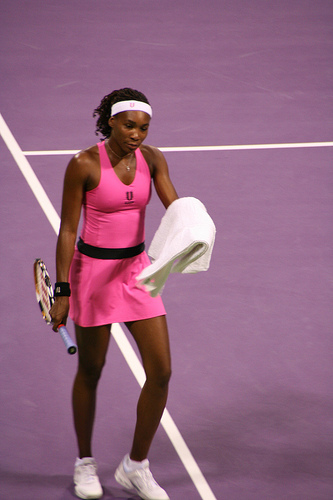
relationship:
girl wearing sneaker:
[48, 87, 180, 499] [73, 455, 104, 499]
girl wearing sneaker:
[48, 87, 180, 499] [114, 452, 171, 499]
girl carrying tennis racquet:
[48, 87, 180, 499] [33, 258, 78, 356]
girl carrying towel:
[48, 87, 180, 499] [136, 196, 218, 298]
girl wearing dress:
[48, 87, 180, 499] [69, 141, 168, 328]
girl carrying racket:
[48, 87, 180, 499] [33, 258, 78, 356]